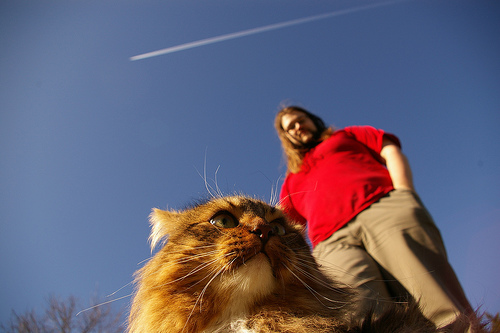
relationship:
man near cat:
[267, 98, 481, 332] [117, 190, 488, 332]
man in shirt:
[267, 98, 481, 332] [272, 129, 418, 211]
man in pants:
[267, 98, 481, 332] [299, 202, 478, 332]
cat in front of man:
[117, 190, 488, 332] [267, 98, 481, 332]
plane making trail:
[122, 56, 136, 63] [112, 4, 385, 67]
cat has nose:
[117, 190, 488, 332] [249, 219, 272, 242]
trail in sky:
[112, 4, 385, 67] [1, 1, 499, 329]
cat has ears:
[117, 190, 488, 332] [122, 202, 318, 242]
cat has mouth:
[117, 190, 488, 332] [235, 242, 283, 280]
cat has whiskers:
[117, 190, 488, 332] [102, 254, 405, 321]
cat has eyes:
[117, 190, 488, 332] [203, 208, 291, 237]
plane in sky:
[122, 56, 136, 63] [1, 1, 499, 329]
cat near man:
[117, 190, 488, 332] [267, 98, 481, 332]